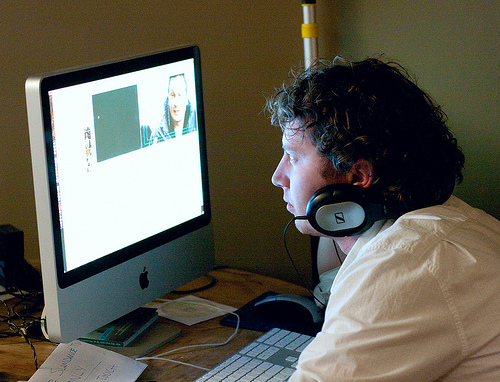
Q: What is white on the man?
A: Shirt.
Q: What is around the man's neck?
A: Headphones.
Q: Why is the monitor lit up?
A: Turned on.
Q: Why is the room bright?
A: Monitor is turned on.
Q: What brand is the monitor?
A: Apple.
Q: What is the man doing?
A: Working.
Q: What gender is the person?
A: Male.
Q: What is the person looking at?
A: Computer monitor.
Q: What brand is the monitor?
A: Apple.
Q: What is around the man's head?
A: Headphones.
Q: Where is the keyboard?
A: In front of the man.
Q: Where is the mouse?
A: Right side of the keyboard.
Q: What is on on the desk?
A: The monitor.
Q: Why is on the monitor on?
A: So he can see it.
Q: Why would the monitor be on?
A: So he can see it.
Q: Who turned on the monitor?
A: The man in front of it.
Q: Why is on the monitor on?
A: So he can see it.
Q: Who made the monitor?
A: Apple computers.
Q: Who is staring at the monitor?
A: The man.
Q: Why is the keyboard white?
A: To make it easier to see.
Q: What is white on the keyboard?
A: The keys.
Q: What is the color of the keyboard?
A: White.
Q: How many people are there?
A: 1.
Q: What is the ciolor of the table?
A: Brown.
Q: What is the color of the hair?
A: Black.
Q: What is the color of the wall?
A: Green.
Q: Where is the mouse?
A: Table.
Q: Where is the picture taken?
A: On his computer.